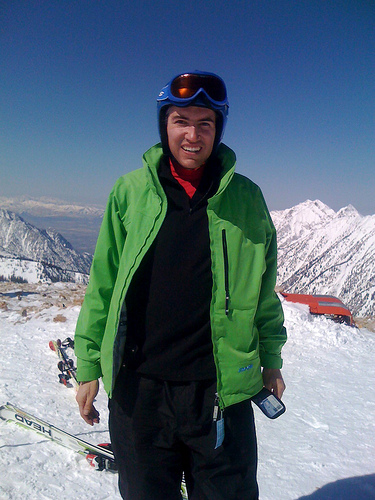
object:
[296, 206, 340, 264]
ice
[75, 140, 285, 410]
green jacket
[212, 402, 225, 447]
tag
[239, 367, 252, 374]
letters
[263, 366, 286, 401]
hand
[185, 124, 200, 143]
nose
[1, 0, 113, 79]
skis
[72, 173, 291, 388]
closed door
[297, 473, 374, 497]
shadow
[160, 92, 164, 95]
letter s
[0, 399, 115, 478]
skis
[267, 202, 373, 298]
mountain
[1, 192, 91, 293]
mountain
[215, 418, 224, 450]
bluetag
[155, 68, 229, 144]
helmet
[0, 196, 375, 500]
snow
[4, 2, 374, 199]
sky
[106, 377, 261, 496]
yellow suitcase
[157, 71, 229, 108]
glasses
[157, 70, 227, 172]
head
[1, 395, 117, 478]
ski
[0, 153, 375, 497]
ground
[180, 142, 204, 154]
smile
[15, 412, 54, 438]
writing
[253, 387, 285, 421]
phone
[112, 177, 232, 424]
zipper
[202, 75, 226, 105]
lenses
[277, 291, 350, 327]
vehicle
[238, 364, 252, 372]
design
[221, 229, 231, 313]
zipper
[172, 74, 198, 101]
lenses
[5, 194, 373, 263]
distance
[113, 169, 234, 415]
shirt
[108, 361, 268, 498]
pants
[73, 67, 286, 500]
man